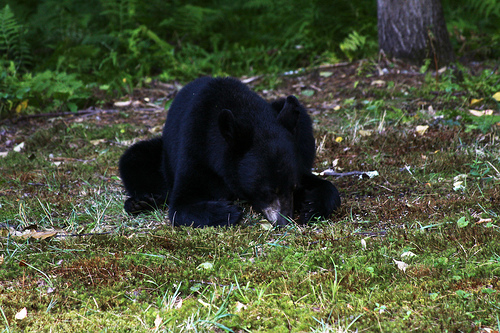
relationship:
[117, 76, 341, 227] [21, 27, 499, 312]
bear on grass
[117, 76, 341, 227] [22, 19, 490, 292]
bear on grass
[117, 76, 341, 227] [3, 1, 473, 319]
bear laying in woods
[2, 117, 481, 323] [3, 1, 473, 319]
ground in woods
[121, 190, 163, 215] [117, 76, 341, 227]
paw on bear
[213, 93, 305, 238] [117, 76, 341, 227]
head of bear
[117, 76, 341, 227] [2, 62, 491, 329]
bear on grass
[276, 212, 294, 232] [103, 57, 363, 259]
nose of bear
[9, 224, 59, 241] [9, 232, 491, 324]
leaf on ground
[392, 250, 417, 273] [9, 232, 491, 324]
leaf on ground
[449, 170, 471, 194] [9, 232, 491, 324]
leaf on ground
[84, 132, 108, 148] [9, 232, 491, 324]
leaf on ground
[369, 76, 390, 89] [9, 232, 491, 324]
leaf on ground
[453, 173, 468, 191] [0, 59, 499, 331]
leaf on ground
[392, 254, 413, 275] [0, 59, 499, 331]
leaf on ground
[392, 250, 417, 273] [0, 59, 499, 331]
leaf on ground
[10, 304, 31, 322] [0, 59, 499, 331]
leaf on ground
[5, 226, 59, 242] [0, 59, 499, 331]
leaf on ground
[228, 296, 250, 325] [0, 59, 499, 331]
leaf on ground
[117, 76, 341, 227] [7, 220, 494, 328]
bear laying on grass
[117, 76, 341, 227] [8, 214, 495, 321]
bear sleeping on grass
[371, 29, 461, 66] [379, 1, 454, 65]
bottom of tree trunk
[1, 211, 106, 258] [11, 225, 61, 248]
branch with leaves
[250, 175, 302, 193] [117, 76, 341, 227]
eyes of bear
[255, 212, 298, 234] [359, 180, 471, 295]
nose to ground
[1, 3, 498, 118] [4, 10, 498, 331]
ferns of woods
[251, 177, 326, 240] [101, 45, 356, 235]
muzzle of bear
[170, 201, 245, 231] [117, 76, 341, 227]
bear's paw of bear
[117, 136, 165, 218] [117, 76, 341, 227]
leg of bear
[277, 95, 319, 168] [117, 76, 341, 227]
black leg of bear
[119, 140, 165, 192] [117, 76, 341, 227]
leg of bear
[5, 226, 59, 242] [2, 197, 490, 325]
leaf on ground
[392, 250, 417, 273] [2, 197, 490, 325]
leaf on ground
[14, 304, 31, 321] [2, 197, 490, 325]
leaf on ground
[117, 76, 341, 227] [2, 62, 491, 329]
bear laying on grass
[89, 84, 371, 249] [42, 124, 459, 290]
bear sleeping on grass